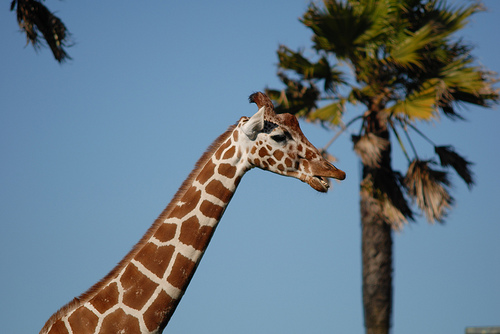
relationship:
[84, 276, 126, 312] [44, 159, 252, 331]
spot on neck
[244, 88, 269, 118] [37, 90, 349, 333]
horn on giraffe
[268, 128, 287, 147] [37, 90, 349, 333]
eyes of giraffe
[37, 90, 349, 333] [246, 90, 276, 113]
giraffe with horn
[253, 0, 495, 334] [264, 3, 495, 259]
palm tree has palm fronds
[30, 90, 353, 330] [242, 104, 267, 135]
giraffe has ear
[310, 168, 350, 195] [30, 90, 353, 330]
giraffe's mouth of giraffe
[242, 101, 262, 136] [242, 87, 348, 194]
ear on head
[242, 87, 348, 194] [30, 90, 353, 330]
head of giraffe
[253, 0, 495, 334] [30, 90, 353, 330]
palm tree behind giraffe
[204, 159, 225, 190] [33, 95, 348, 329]
spot on giraffe neck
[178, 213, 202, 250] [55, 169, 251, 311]
spot on giraffe neck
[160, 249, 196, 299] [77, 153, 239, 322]
spot on giraffe neck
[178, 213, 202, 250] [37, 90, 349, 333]
spot on giraffe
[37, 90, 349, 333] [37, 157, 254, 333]
giraffe on giraffe neck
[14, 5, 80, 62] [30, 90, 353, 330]
leaf over giraffe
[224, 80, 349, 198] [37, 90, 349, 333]
head of giraffe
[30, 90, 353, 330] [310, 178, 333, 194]
giraffe has lip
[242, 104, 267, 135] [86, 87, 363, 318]
ear of giraffe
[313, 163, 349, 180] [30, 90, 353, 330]
lip of a giraffe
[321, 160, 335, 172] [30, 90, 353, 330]
nostril of a giraffe